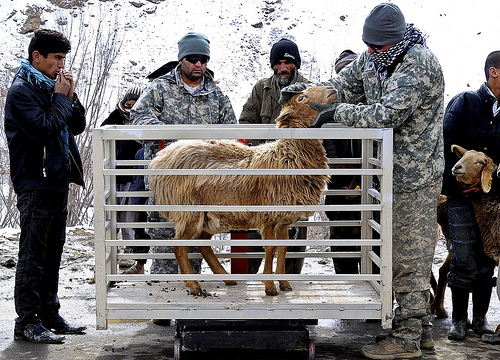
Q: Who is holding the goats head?
A: The soldier.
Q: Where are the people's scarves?
A: On their necks.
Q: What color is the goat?
A: Tan.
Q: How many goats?
A: Two.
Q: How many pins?
A: One.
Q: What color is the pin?
A: Silver.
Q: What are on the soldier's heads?
A: Hats.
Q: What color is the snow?
A: White.